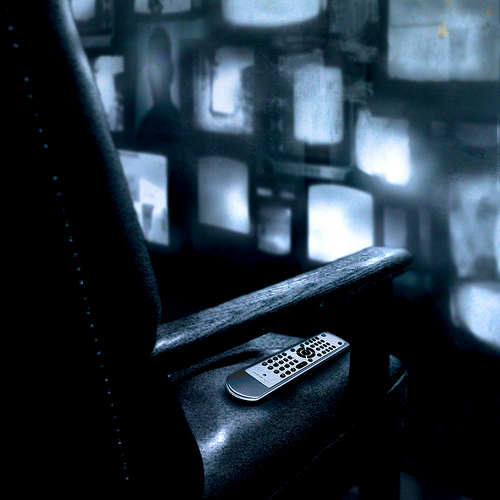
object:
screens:
[190, 45, 256, 136]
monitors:
[303, 185, 380, 263]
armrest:
[152, 241, 427, 373]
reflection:
[198, 420, 245, 462]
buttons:
[261, 334, 336, 379]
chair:
[1, 2, 416, 499]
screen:
[119, 150, 170, 251]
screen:
[221, 0, 325, 27]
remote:
[223, 329, 352, 406]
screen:
[301, 184, 388, 264]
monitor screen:
[135, 31, 177, 120]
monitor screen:
[191, 53, 250, 127]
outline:
[136, 25, 182, 137]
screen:
[346, 108, 426, 194]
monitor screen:
[287, 60, 345, 155]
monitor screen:
[303, 188, 374, 262]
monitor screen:
[120, 147, 178, 244]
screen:
[348, 110, 415, 185]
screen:
[309, 187, 372, 259]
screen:
[256, 202, 293, 252]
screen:
[198, 152, 251, 232]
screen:
[137, 20, 191, 127]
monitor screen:
[259, 173, 305, 260]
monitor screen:
[194, 151, 261, 243]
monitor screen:
[349, 108, 424, 191]